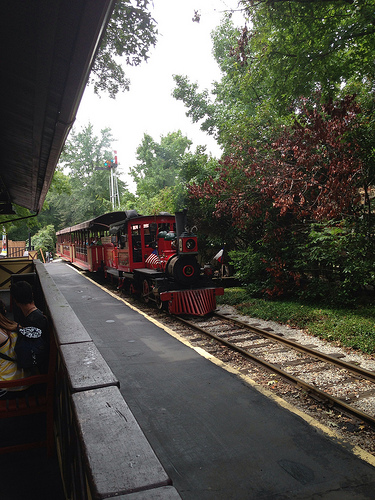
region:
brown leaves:
[257, 148, 340, 207]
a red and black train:
[56, 207, 223, 322]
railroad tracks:
[242, 329, 318, 380]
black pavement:
[150, 363, 219, 435]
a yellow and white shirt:
[0, 324, 15, 379]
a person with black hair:
[9, 278, 37, 312]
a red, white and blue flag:
[143, 244, 161, 269]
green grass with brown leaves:
[318, 307, 372, 335]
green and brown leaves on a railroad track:
[248, 366, 291, 393]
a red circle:
[178, 261, 195, 280]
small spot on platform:
[89, 304, 131, 341]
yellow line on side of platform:
[176, 333, 274, 435]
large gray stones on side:
[65, 379, 176, 497]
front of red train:
[142, 278, 237, 326]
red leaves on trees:
[261, 173, 332, 213]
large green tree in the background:
[25, 218, 74, 281]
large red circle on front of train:
[173, 256, 200, 279]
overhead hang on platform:
[29, 155, 79, 231]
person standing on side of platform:
[19, 300, 54, 370]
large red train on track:
[53, 189, 251, 364]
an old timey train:
[41, 187, 245, 331]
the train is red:
[50, 210, 249, 348]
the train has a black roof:
[60, 206, 176, 234]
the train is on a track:
[115, 198, 274, 396]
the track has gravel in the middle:
[202, 314, 314, 391]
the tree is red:
[248, 164, 319, 238]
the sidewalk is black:
[87, 289, 117, 332]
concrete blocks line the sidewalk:
[41, 294, 130, 440]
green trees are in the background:
[32, 222, 53, 257]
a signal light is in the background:
[98, 152, 123, 209]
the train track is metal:
[185, 324, 371, 476]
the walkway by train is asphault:
[90, 312, 364, 494]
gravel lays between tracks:
[219, 312, 369, 398]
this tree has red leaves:
[208, 105, 349, 220]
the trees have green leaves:
[209, 3, 371, 88]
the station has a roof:
[1, 3, 79, 218]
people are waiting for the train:
[0, 275, 50, 407]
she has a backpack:
[11, 317, 54, 382]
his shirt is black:
[9, 307, 53, 333]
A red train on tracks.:
[36, 197, 262, 334]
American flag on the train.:
[141, 243, 171, 269]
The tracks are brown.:
[218, 303, 373, 421]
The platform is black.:
[137, 358, 278, 492]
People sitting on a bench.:
[0, 271, 76, 384]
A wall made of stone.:
[34, 358, 159, 495]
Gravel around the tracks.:
[257, 315, 345, 402]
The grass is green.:
[304, 298, 367, 341]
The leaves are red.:
[245, 98, 356, 221]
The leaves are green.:
[264, 13, 370, 78]